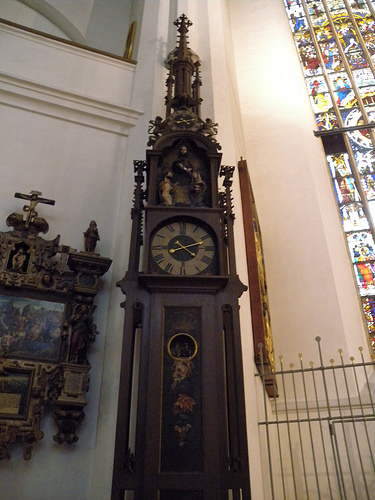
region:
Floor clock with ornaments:
[108, 3, 252, 498]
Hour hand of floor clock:
[181, 236, 207, 247]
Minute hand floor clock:
[166, 243, 181, 252]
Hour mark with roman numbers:
[151, 220, 215, 274]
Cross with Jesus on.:
[12, 184, 57, 238]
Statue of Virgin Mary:
[81, 215, 107, 255]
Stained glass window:
[286, 0, 373, 327]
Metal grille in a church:
[253, 338, 373, 498]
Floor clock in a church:
[2, 0, 373, 494]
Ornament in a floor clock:
[153, 137, 209, 206]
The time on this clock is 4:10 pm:
[136, 205, 230, 283]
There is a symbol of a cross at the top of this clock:
[172, 12, 192, 35]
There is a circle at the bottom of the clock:
[167, 332, 197, 366]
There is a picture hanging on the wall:
[1, 291, 68, 364]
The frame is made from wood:
[1, 189, 112, 464]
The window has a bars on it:
[284, 0, 374, 363]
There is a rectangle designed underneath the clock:
[164, 303, 205, 499]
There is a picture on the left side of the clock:
[236, 156, 282, 400]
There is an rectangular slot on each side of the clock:
[127, 298, 240, 474]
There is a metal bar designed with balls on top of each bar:
[251, 336, 373, 499]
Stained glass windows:
[301, 65, 373, 156]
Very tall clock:
[141, 9, 222, 317]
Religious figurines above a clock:
[148, 130, 218, 208]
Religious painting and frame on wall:
[7, 170, 90, 437]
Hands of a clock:
[148, 215, 220, 275]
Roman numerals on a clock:
[172, 221, 217, 271]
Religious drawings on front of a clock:
[154, 295, 218, 468]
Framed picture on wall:
[233, 148, 293, 421]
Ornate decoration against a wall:
[249, 337, 373, 469]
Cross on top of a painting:
[9, 175, 57, 231]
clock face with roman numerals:
[148, 218, 216, 276]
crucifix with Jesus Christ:
[12, 189, 54, 231]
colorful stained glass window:
[304, 72, 372, 231]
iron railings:
[252, 334, 373, 498]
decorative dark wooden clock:
[115, 12, 248, 493]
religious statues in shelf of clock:
[156, 144, 208, 207]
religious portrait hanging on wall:
[1, 292, 66, 364]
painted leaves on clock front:
[171, 392, 196, 411]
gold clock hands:
[166, 238, 202, 258]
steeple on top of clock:
[163, 11, 203, 114]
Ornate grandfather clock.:
[109, 14, 251, 498]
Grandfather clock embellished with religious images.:
[105, 9, 256, 498]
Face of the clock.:
[144, 209, 222, 279]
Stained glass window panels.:
[283, 0, 373, 362]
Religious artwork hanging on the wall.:
[0, 186, 113, 460]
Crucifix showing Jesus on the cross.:
[11, 189, 56, 233]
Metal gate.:
[257, 334, 374, 499]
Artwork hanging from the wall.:
[236, 156, 281, 399]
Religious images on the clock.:
[145, 129, 222, 209]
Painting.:
[1, 292, 67, 364]